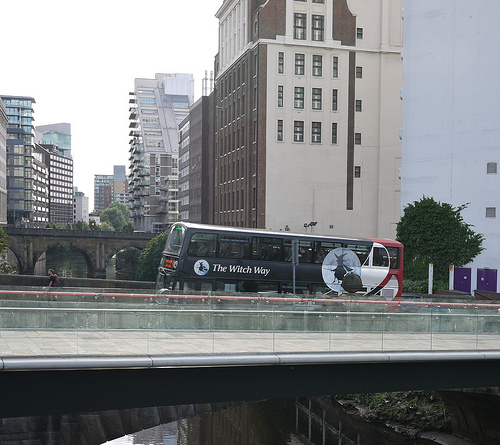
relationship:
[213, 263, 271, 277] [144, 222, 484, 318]
print on bus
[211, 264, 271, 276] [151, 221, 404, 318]
print on bus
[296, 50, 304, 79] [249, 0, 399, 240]
window on building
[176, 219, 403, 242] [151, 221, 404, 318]
top of bus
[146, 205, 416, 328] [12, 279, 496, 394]
bus on bridge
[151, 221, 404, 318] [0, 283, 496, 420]
bus on bridge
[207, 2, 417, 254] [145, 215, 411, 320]
building behind bus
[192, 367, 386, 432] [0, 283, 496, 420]
water under bridge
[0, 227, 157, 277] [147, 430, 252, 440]
bridge across water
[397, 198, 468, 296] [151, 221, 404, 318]
tree behind bus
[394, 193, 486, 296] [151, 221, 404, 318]
tree near bus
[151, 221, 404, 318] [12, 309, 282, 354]
bus on road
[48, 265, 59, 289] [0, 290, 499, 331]
man on street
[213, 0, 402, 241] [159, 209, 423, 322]
building by bus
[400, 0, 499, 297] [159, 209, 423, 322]
building by bus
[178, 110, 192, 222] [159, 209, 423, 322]
building by bus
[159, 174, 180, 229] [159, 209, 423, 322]
building by bus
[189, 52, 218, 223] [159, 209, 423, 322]
building by bus